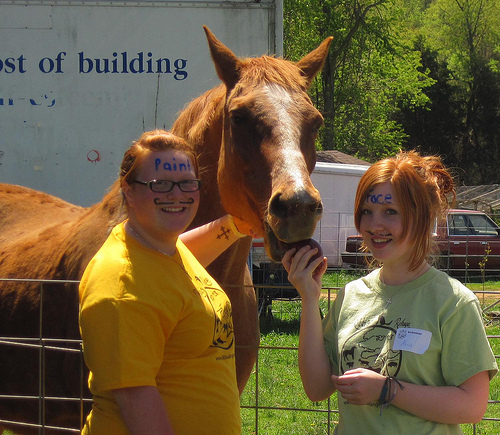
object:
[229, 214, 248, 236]
wrist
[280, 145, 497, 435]
girl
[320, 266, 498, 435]
shirt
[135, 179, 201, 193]
glasses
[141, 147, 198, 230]
face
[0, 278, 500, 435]
fence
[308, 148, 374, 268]
building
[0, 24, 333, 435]
horse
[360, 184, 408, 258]
face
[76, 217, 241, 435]
shirt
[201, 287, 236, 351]
print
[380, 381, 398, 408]
bracelets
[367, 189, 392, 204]
blue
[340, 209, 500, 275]
car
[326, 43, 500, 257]
background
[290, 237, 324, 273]
apple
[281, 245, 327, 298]
hand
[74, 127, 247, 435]
girl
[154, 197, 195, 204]
mustache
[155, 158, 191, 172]
paint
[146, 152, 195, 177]
forehead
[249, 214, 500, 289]
fence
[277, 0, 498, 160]
trees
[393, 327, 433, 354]
nametag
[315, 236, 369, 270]
trailer